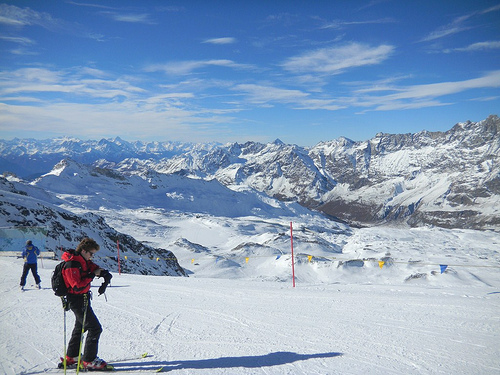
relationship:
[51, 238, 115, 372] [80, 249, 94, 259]
man wearing ski goggles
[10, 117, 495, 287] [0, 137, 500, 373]
mountain covered in snow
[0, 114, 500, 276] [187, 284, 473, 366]
mountain covered in snow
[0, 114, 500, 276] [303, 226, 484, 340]
mountain covered in snow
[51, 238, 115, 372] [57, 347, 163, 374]
man wearing ski shoes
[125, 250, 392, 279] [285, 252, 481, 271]
flags on rope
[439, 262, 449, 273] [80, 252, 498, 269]
flag on rope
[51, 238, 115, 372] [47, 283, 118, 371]
man with ski poles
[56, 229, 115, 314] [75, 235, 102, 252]
man with hair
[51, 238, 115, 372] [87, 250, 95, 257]
man wearing ski goggles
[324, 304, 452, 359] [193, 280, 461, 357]
snow on ground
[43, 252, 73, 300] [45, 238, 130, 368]
backpack on person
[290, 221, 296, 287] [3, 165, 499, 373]
pole on snow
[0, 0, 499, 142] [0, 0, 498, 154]
cloud in blue sky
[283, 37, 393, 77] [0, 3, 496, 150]
cloud in sky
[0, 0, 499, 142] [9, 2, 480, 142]
cloud in sky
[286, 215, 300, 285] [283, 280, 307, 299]
pole in ground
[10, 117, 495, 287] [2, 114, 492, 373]
mountain covered in snow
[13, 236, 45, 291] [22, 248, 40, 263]
person in jacket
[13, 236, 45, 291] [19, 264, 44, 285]
person in pants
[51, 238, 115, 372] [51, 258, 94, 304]
man wearing backpack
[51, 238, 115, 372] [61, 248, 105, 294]
man in red jacket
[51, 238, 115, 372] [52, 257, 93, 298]
man wearing backpack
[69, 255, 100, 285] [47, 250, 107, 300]
skier wearing red jacket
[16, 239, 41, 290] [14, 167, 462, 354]
person on mountain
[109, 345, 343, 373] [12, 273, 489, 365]
shadow in snow